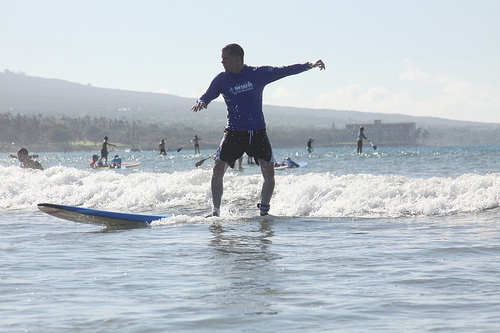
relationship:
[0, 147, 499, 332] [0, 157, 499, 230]
water behind wave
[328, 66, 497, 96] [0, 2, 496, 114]
cloud in sky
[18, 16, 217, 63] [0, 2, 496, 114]
cloud in sky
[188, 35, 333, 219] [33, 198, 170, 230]
man on surfboard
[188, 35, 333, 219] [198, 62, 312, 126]
man wearing shirt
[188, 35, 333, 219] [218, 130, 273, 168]
man wearing shorts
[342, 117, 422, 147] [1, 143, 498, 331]
building past water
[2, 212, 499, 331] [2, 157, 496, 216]
water ahead of wave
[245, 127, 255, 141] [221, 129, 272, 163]
tie string on shorts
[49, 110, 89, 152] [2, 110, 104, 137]
tree in woods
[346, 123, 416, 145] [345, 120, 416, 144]
wall on building